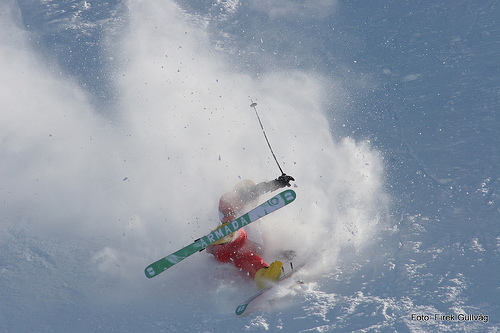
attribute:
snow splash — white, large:
[2, 1, 387, 332]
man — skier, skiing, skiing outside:
[208, 172, 298, 288]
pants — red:
[205, 228, 266, 274]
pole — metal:
[248, 96, 297, 177]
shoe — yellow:
[254, 262, 282, 289]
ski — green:
[142, 186, 296, 287]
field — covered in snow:
[5, 2, 495, 330]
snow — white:
[2, 3, 495, 332]